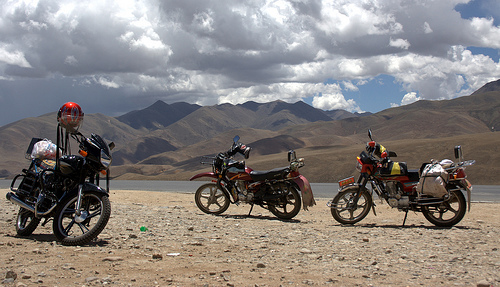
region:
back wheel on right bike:
[432, 200, 467, 227]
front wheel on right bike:
[330, 187, 369, 226]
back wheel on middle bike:
[268, 185, 303, 218]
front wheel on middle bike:
[190, 186, 226, 213]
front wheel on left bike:
[62, 195, 107, 242]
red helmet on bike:
[56, 100, 86, 114]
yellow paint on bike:
[393, 163, 400, 173]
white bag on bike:
[429, 177, 439, 188]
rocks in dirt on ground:
[242, 237, 276, 272]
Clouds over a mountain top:
[157, 27, 388, 135]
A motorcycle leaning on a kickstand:
[355, 128, 421, 231]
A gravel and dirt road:
[187, 212, 239, 285]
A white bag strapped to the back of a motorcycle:
[407, 126, 475, 226]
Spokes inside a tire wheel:
[195, 183, 231, 210]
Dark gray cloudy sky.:
[210, 49, 257, 88]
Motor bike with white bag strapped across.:
[329, 130, 474, 225]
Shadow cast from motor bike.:
[367, 218, 445, 233]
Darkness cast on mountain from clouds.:
[121, 95, 194, 127]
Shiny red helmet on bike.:
[55, 100, 85, 131]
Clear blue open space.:
[359, 81, 397, 106]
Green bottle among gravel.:
[136, 220, 149, 237]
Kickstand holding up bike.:
[400, 212, 411, 227]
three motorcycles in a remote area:
[2, 1, 494, 282]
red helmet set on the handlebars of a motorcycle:
[55, 100, 85, 130]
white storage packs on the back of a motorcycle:
[417, 155, 454, 201]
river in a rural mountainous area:
[3, 175, 493, 204]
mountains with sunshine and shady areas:
[3, 78, 494, 173]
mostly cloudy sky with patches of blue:
[2, 2, 494, 104]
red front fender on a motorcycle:
[187, 170, 229, 187]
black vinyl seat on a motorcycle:
[252, 163, 289, 180]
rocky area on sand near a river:
[117, 211, 489, 284]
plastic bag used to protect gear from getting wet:
[29, 138, 63, 160]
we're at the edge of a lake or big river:
[1, 167, 497, 205]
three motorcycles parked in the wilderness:
[4, 92, 479, 251]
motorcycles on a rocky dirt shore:
[2, 183, 497, 280]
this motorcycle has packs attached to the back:
[414, 150, 456, 202]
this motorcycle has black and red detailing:
[186, 128, 319, 221]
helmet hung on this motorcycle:
[52, 97, 89, 134]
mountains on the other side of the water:
[3, 73, 498, 180]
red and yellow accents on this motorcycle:
[325, 124, 480, 229]